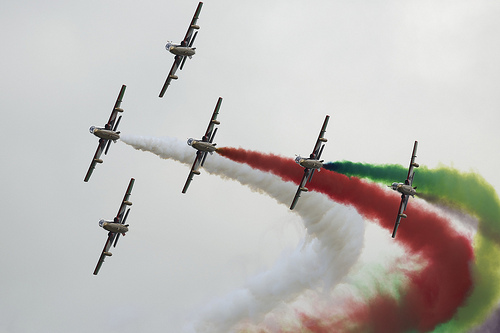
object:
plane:
[82, 83, 129, 184]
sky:
[1, 1, 499, 333]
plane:
[158, 0, 205, 99]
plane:
[91, 176, 136, 276]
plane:
[180, 95, 224, 195]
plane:
[289, 115, 331, 212]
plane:
[390, 139, 421, 239]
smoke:
[116, 134, 500, 333]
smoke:
[418, 193, 500, 331]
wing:
[104, 83, 128, 131]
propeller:
[164, 40, 175, 54]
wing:
[84, 138, 108, 182]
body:
[96, 218, 133, 236]